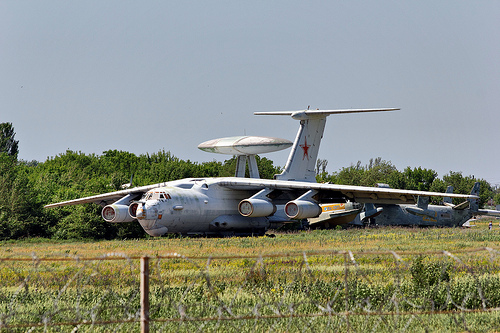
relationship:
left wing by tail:
[329, 106, 404, 116] [275, 118, 328, 179]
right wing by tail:
[252, 107, 295, 120] [275, 118, 328, 179]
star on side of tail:
[300, 137, 313, 163] [275, 118, 328, 179]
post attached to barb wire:
[139, 253, 152, 332] [0, 245, 499, 331]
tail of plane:
[275, 118, 328, 179] [41, 108, 481, 239]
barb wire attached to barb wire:
[2, 306, 499, 329] [0, 245, 499, 331]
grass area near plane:
[1, 227, 499, 257] [41, 108, 481, 239]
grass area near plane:
[1, 227, 499, 257] [322, 180, 484, 228]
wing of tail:
[252, 107, 295, 120] [275, 118, 328, 179]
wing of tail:
[329, 106, 404, 116] [275, 118, 328, 179]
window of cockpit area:
[157, 191, 165, 200] [137, 190, 174, 205]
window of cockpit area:
[140, 193, 148, 198] [137, 190, 174, 205]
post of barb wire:
[139, 253, 152, 332] [0, 245, 499, 331]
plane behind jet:
[322, 180, 484, 228] [41, 108, 481, 239]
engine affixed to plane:
[236, 188, 279, 219] [41, 108, 481, 239]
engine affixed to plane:
[284, 190, 323, 220] [41, 108, 481, 239]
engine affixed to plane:
[101, 197, 128, 225] [41, 108, 481, 239]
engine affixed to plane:
[127, 200, 139, 218] [41, 108, 481, 239]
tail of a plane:
[275, 118, 328, 179] [41, 108, 481, 239]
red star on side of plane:
[300, 137, 313, 163] [41, 108, 481, 239]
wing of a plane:
[219, 173, 480, 200] [41, 108, 481, 239]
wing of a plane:
[42, 176, 164, 213] [41, 108, 481, 239]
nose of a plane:
[134, 198, 148, 224] [41, 108, 481, 239]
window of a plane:
[157, 191, 165, 200] [41, 108, 481, 239]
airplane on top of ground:
[41, 108, 481, 239] [1, 227, 499, 257]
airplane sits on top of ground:
[41, 108, 481, 239] [1, 227, 499, 257]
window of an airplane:
[157, 191, 165, 200] [41, 108, 481, 239]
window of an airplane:
[140, 193, 148, 198] [41, 108, 481, 239]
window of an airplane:
[148, 193, 155, 202] [41, 108, 481, 239]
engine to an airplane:
[236, 188, 279, 219] [41, 108, 481, 239]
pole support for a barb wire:
[139, 253, 152, 332] [0, 245, 499, 331]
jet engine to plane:
[236, 188, 279, 219] [41, 108, 481, 239]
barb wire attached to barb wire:
[0, 245, 499, 331] [0, 245, 499, 331]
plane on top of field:
[41, 108, 481, 239] [1, 227, 498, 332]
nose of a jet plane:
[134, 198, 148, 224] [41, 108, 481, 239]